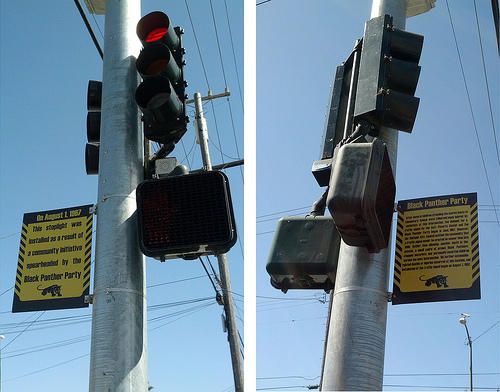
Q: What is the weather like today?
A: It is cloudless.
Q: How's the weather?
A: It is cloudless.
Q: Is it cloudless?
A: Yes, it is cloudless.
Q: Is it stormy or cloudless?
A: It is cloudless.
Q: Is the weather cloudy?
A: No, it is cloudless.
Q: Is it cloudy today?
A: No, it is cloudless.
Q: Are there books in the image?
A: No, there are no books.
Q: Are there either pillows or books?
A: No, there are no books or pillows.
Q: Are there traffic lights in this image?
A: Yes, there is a traffic light.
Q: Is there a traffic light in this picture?
A: Yes, there is a traffic light.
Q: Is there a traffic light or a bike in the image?
A: Yes, there is a traffic light.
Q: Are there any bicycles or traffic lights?
A: Yes, there is a traffic light.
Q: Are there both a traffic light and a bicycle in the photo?
A: No, there is a traffic light but no bicycles.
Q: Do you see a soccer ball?
A: No, there are no soccer balls.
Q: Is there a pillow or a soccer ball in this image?
A: No, there are no soccer balls or pillows.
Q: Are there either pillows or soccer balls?
A: No, there are no soccer balls or pillows.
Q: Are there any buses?
A: No, there are no buses.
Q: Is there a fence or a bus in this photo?
A: No, there are no buses or fences.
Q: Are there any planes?
A: No, there are no planes.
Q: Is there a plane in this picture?
A: No, there are no airplanes.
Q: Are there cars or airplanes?
A: No, there are no airplanes or cars.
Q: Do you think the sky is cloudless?
A: Yes, the sky is cloudless.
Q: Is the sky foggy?
A: No, the sky is cloudless.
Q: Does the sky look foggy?
A: No, the sky is cloudless.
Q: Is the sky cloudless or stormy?
A: The sky is cloudless.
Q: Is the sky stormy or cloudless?
A: The sky is cloudless.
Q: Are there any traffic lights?
A: Yes, there is a traffic light.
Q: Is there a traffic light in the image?
A: Yes, there is a traffic light.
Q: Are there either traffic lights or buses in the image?
A: Yes, there is a traffic light.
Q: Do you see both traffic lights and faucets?
A: No, there is a traffic light but no faucets.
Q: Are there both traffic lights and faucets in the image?
A: No, there is a traffic light but no faucets.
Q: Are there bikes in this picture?
A: No, there are no bikes.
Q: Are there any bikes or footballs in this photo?
A: No, there are no bikes or footballs.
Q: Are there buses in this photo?
A: No, there are no buses.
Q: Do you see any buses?
A: No, there are no buses.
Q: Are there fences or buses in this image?
A: No, there are no buses or fences.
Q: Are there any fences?
A: No, there are no fences.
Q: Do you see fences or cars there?
A: No, there are no fences or cars.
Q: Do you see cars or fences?
A: No, there are no fences or cars.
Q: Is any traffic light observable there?
A: Yes, there is a traffic light.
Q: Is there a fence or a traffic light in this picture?
A: Yes, there is a traffic light.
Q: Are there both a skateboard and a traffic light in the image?
A: No, there is a traffic light but no skateboards.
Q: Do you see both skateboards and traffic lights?
A: No, there is a traffic light but no skateboards.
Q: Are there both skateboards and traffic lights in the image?
A: No, there is a traffic light but no skateboards.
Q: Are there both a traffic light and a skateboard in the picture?
A: No, there is a traffic light but no skateboards.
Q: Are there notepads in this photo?
A: No, there are no notepads.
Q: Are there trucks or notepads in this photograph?
A: No, there are no notepads or trucks.